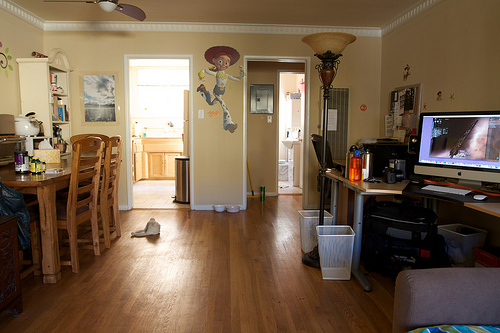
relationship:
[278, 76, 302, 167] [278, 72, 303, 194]
light in bathroom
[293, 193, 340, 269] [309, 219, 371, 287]
basket on basket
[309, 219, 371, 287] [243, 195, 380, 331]
basket on floor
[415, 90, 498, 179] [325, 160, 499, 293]
computer on a desk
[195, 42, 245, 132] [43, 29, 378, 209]
picture on wall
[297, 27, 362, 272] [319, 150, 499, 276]
lamp next to desk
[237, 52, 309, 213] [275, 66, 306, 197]
doorway into bathroom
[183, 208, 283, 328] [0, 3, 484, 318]
floors in house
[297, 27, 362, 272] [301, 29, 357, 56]
lamp with shade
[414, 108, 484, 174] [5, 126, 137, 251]
computer monitor on desk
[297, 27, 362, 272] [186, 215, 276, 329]
lamp on floor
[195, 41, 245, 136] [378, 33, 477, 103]
decal on wall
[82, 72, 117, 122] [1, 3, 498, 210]
picture on wall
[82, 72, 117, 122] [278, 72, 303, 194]
picture in bathroom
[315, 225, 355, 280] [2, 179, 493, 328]
basket on floor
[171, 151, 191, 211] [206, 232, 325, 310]
can on floor